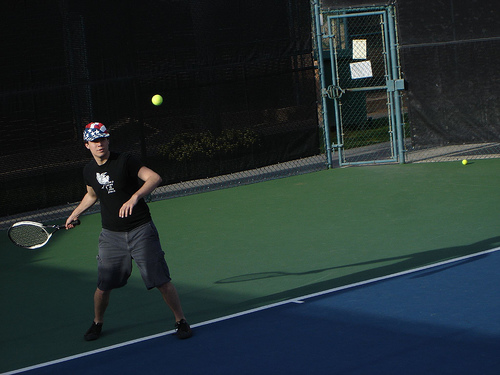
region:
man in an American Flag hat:
[19, 49, 306, 365]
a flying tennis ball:
[121, 93, 219, 154]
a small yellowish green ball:
[139, 78, 165, 117]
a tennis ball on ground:
[412, 90, 495, 188]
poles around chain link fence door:
[313, 3, 410, 167]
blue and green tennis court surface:
[0, 156, 498, 372]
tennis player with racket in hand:
[8, 120, 191, 340]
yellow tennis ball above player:
[65, 93, 190, 341]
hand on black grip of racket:
[8, 215, 81, 250]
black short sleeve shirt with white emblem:
[84, 153, 151, 230]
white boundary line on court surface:
[2, 245, 498, 373]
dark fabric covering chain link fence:
[393, 0, 499, 159]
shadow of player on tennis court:
[100, 235, 497, 337]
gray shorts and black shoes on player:
[84, 219, 192, 341]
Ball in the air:
[143, 89, 172, 115]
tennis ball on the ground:
[457, 153, 474, 170]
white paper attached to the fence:
[342, 30, 373, 60]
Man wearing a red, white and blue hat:
[76, 115, 117, 150]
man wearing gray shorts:
[91, 217, 175, 296]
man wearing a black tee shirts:
[71, 159, 157, 230]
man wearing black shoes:
[167, 315, 195, 342]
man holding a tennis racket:
[7, 209, 87, 258]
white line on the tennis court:
[301, 257, 451, 314]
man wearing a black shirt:
[68, 167, 179, 239]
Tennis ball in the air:
[143, 90, 167, 112]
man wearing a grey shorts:
[86, 222, 178, 297]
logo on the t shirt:
[90, 170, 116, 196]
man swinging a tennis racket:
[1, 215, 88, 245]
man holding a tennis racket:
[4, 210, 82, 247]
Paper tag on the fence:
[350, 34, 367, 61]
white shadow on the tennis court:
[281, 288, 307, 310]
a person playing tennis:
[5, 83, 205, 344]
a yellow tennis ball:
[148, 91, 165, 107]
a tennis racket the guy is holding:
[4, 215, 84, 252]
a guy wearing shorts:
[6, 118, 201, 345]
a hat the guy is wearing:
[78, 118, 114, 144]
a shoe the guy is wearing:
[80, 319, 109, 344]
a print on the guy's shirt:
[93, 168, 115, 195]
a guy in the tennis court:
[3, 87, 347, 358]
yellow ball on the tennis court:
[458, 154, 468, 166]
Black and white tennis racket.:
[8, 219, 80, 251]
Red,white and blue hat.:
[81, 121, 108, 141]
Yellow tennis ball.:
[151, 92, 163, 107]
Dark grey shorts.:
[94, 220, 171, 292]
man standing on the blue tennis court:
[52, 120, 195, 349]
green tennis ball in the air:
[147, 92, 164, 110]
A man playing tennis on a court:
[4, 107, 201, 352]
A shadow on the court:
[215, 258, 427, 283]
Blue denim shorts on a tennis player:
[90, 218, 167, 298]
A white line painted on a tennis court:
[248, 260, 493, 295]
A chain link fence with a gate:
[323, 9, 497, 167]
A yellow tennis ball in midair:
[145, 92, 165, 107]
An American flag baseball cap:
[82, 121, 113, 140]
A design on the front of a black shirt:
[92, 171, 119, 196]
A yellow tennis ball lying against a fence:
[458, 155, 471, 164]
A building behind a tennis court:
[11, 4, 499, 154]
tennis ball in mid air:
[150, 93, 162, 105]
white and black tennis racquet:
[8, 218, 80, 250]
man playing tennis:
[67, 121, 193, 341]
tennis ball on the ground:
[461, 159, 468, 165]